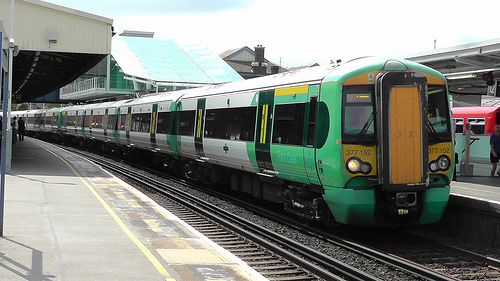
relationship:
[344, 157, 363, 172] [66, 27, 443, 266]
headlight on train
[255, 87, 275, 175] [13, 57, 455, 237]
door on train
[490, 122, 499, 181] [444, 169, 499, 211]
man on train platform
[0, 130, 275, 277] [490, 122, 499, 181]
train platform on man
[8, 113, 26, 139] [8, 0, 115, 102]
people under awning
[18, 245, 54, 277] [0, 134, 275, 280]
shadow on train platform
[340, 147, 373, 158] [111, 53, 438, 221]
377 152 on front of train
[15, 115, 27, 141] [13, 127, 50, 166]
people at waiting bay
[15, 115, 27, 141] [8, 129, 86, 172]
people at waiting bay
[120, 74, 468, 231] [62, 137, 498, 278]
train on track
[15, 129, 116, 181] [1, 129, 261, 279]
pavement shadow on pavement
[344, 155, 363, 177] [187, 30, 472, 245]
headlight on front of train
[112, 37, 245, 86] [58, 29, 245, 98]
roof of building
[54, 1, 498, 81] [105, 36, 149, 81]
sky full of cloud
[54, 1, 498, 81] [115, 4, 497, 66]
sky full of cloud